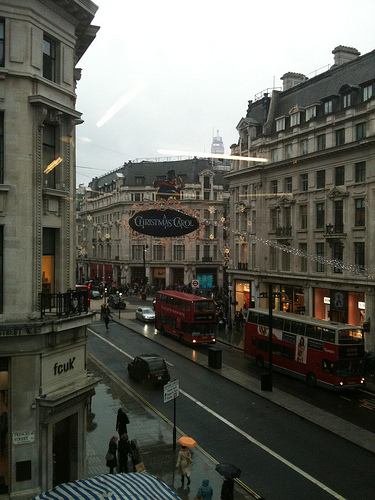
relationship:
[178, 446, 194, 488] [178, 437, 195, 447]
woman carrying umbrella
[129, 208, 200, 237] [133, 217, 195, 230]
sign reading christmas carol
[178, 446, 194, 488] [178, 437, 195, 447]
pedestrian carrying umbrella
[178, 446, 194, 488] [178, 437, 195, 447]
person walking umbrella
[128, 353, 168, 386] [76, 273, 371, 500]
vehicle driving on road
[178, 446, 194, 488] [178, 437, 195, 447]
person holding umbrella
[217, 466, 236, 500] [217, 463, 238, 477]
person holding umbrella